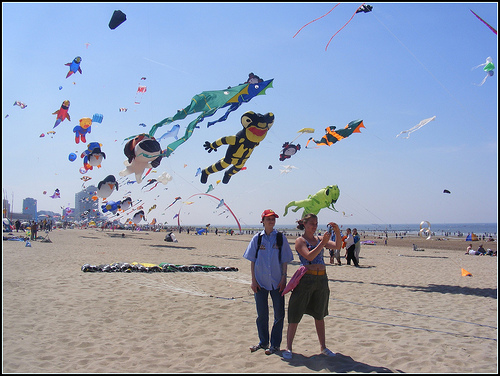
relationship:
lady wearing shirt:
[282, 211, 342, 361] [297, 234, 325, 266]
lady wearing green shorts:
[282, 211, 342, 360] [286, 271, 328, 324]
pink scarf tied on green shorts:
[279, 265, 306, 299] [286, 271, 328, 325]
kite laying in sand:
[73, 243, 260, 289] [26, 283, 232, 372]